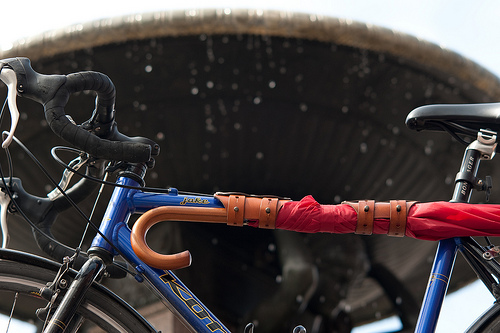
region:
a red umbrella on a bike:
[127, 185, 493, 280]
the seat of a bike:
[404, 87, 499, 140]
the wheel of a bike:
[0, 244, 168, 331]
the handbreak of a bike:
[0, 65, 25, 156]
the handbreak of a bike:
[0, 187, 13, 250]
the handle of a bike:
[46, 74, 161, 177]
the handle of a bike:
[30, 186, 148, 288]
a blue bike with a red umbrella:
[1, 52, 496, 332]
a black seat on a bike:
[401, 94, 498, 149]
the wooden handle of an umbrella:
[126, 197, 251, 273]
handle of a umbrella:
[123, 194, 214, 274]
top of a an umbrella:
[277, 177, 496, 263]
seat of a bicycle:
[395, 96, 498, 138]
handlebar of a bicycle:
[8, 42, 158, 176]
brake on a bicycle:
[1, 64, 21, 151]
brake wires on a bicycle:
[0, 117, 174, 289]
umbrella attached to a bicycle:
[127, 174, 498, 280]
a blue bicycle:
[6, 37, 498, 330]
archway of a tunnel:
[0, 8, 494, 101]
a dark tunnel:
[16, 59, 466, 189]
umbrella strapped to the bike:
[102, 167, 495, 280]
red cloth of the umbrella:
[265, 186, 497, 246]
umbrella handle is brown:
[112, 200, 238, 276]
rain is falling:
[155, 32, 345, 141]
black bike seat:
[401, 88, 498, 140]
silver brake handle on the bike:
[0, 68, 27, 152]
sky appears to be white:
[416, 13, 486, 39]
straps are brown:
[388, 193, 406, 237]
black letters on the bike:
[149, 265, 244, 331]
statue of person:
[279, 239, 370, 318]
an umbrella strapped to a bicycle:
[131, 192, 497, 274]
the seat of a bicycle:
[404, 95, 497, 135]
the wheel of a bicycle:
[1, 250, 153, 329]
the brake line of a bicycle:
[52, 140, 209, 200]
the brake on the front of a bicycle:
[27, 252, 77, 317]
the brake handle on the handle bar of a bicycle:
[0, 52, 40, 153]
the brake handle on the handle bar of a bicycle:
[0, 148, 22, 255]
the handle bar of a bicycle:
[21, 64, 153, 172]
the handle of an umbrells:
[128, 199, 218, 271]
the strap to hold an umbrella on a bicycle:
[218, 187, 288, 232]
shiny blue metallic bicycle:
[0, 43, 492, 331]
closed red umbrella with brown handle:
[121, 178, 498, 288]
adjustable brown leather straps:
[214, 185, 425, 256]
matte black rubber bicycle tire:
[0, 245, 167, 332]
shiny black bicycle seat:
[395, 89, 497, 157]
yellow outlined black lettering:
[145, 255, 229, 330]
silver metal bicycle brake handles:
[1, 65, 31, 150]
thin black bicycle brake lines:
[0, 123, 188, 307]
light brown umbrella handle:
[117, 201, 239, 279]